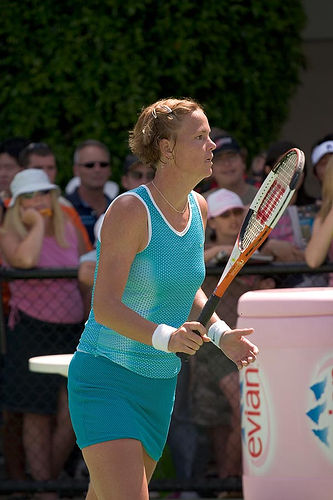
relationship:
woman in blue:
[60, 84, 234, 487] [69, 180, 206, 453]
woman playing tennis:
[60, 84, 234, 487] [52, 73, 300, 496]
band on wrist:
[147, 321, 177, 352] [140, 316, 180, 353]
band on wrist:
[147, 321, 177, 352] [149, 320, 180, 361]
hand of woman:
[169, 321, 209, 354] [60, 84, 234, 487]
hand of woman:
[219, 328, 258, 369] [60, 84, 234, 487]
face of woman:
[174, 103, 224, 191] [17, 68, 260, 481]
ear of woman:
[154, 133, 172, 162] [142, 94, 218, 203]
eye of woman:
[196, 132, 204, 139] [60, 84, 234, 487]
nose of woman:
[206, 137, 217, 152] [60, 84, 234, 487]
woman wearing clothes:
[60, 84, 234, 487] [62, 178, 210, 468]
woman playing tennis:
[60, 84, 234, 487] [57, 84, 323, 497]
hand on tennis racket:
[169, 321, 209, 354] [179, 147, 305, 363]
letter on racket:
[253, 177, 286, 224] [193, 103, 313, 369]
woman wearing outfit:
[60, 84, 234, 487] [64, 193, 217, 450]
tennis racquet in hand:
[169, 143, 306, 360] [167, 324, 205, 359]